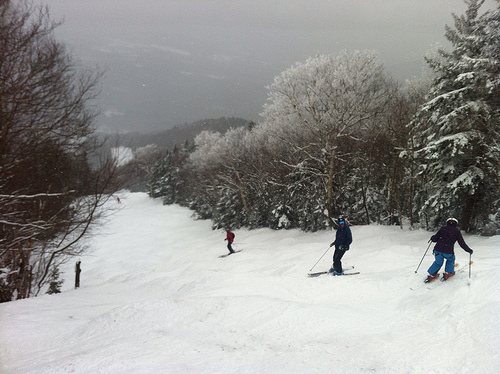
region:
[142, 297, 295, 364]
ground covered with white snow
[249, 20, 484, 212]
trees covered with snow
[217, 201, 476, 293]
three people skiing down a hill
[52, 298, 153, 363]
tracks in the snow from skiers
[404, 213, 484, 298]
skier holding a ski pole in each hand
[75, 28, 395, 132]
mountains in the distance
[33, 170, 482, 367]
ski course down a mountain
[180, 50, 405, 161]
tops of trees covered with white snow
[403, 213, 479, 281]
person wearing light blue ski pants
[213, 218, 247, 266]
person wearing a red ski jacket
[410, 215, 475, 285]
a person on skis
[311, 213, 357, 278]
a person watching someone skiing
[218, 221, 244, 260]
a person wearing a red jacket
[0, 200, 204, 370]
a patch of white cold snow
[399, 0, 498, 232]
a big bushy pine tree with snow on the branches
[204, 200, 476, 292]
people skiing down a snowy hill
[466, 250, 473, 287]
a skiing pole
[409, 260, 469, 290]
a pair of skis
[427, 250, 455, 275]
a pair of blue snow pants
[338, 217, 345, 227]
a blue hat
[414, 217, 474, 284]
a person snow skiing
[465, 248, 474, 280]
a skier's right pole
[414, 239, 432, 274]
a skier's left pole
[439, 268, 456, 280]
a skier's right ski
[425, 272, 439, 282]
a skier's left ski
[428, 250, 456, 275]
a skier's blue snow pants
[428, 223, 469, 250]
a skier's dark jacket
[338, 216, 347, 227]
a skier's sunglasses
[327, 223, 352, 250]
a skier's black ski jacket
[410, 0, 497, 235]
a snow covered tree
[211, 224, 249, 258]
skier wearing a red coat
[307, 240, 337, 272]
ski pole in a person's hand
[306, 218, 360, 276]
skier dressed in dark colored clothing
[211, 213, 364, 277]
two skiers on snow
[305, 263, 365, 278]
skis on a person's feet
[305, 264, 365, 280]
pair of skis on the snow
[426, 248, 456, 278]
blue pants on a skier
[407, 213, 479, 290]
skier with holding two poles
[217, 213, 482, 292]
three skiers on snow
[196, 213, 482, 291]
three people skiing